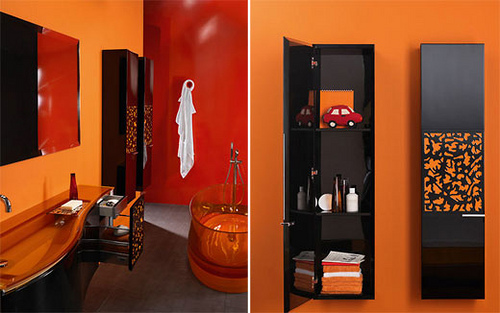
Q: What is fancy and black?
A: Cabinet.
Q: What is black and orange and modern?
A: Tub.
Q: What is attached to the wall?
A: Shelving.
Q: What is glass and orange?
A: Tub.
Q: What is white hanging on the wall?
A: Towel.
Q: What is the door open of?
A: Shelf.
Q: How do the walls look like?
A: Orange.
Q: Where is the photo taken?
A: Bathroom.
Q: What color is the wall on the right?
A: Orange.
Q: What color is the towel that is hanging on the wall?
A: White.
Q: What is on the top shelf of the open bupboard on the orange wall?
A: Red car.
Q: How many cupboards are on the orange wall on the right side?
A: Two.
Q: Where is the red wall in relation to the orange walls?
A: Middle.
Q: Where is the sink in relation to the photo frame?
A: Left.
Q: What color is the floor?
A: Gray.